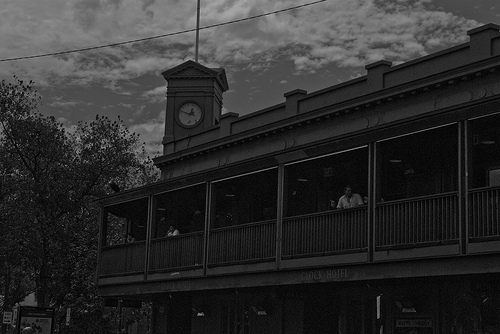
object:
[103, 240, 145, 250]
rail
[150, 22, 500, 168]
roof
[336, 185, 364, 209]
man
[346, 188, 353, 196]
face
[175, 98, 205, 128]
clock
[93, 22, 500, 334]
building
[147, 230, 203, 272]
fence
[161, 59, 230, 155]
tower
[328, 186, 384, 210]
people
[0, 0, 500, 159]
sky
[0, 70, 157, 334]
trees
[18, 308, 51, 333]
sign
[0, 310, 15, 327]
advertisement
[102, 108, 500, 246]
windows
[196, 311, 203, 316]
light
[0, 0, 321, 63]
wire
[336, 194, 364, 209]
shirt